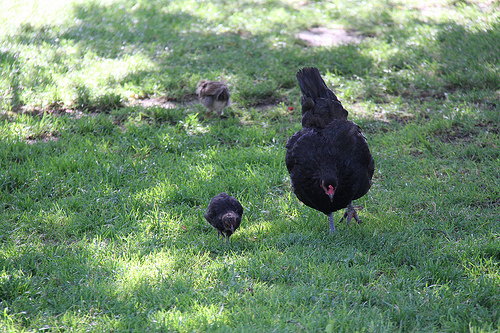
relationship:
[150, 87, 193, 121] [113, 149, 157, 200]
dirt in grass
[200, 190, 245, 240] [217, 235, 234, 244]
chicken has foot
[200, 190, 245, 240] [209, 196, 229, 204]
chicken has tail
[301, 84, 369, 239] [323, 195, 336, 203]
chicken has beak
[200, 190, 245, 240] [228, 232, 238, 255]
chicken has leg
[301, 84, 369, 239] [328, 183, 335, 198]
chicken has comb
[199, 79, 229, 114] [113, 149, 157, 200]
bird in grass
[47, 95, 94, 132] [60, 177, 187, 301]
shadow on ground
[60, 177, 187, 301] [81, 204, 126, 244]
ground has spot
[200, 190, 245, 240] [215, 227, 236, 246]
chicken has feet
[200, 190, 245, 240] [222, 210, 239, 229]
chicken has head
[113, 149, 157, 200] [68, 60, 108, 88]
grass has light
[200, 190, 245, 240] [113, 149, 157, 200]
chicken in grass